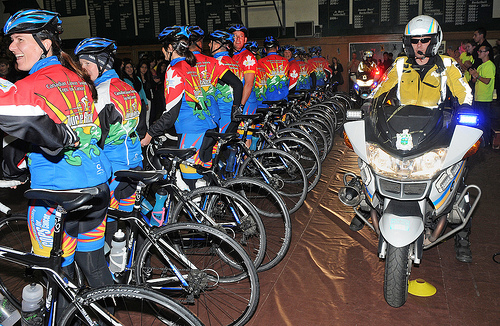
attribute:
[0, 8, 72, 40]
helmet — blue, black, for biking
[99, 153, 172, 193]
seat — black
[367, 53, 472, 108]
jacket — red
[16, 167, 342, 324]
bikes — black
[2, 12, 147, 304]
man — light skinned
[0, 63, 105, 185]
blouse — blue, red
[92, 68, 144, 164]
blouse — blue, red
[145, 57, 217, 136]
blouse — blue, red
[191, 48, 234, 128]
blouse — blue, red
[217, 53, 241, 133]
blouse — blue, red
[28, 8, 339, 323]
people — lined up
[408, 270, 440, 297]
oplate — yellow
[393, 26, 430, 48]
helmet — blue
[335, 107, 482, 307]
motor bike — white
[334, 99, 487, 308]
motorcycle — white